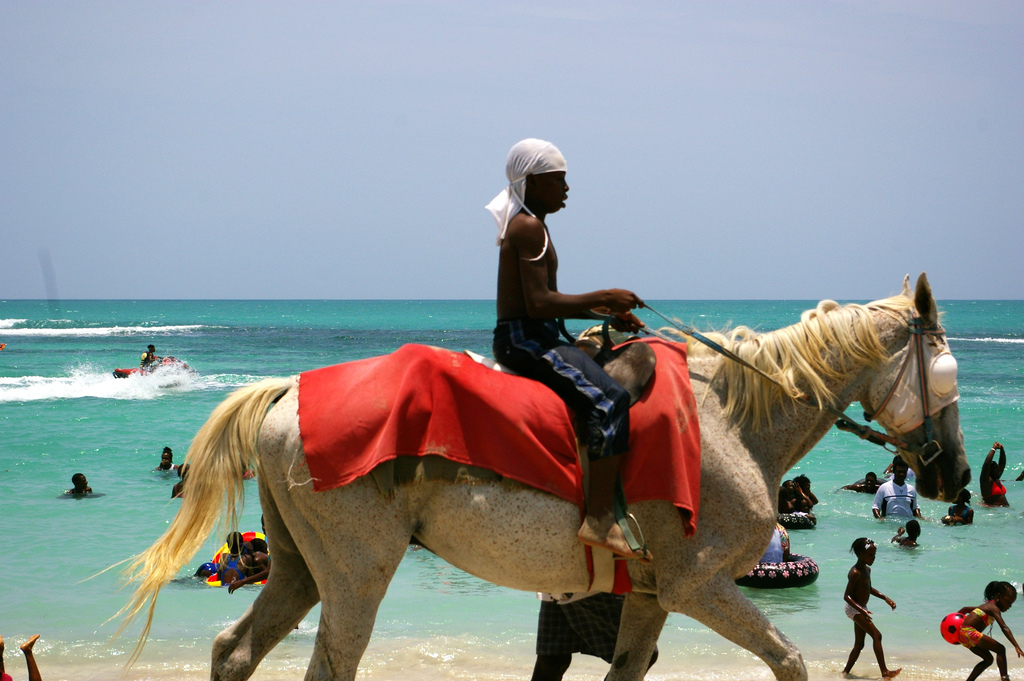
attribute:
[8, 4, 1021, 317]
sky — blue, white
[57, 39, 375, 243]
clouds — white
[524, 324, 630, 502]
pants — blue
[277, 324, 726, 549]
blanket — red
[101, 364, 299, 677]
tail — golden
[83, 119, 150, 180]
clouds — white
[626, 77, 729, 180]
clouds — white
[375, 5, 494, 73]
clouds — white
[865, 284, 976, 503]
face — brown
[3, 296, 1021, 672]
water — bright blue